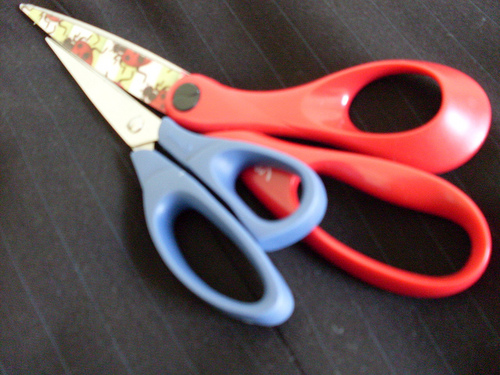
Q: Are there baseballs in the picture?
A: No, there are no baseballs.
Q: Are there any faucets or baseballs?
A: No, there are no baseballs or faucets.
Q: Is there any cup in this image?
A: No, there are no cups.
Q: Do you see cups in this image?
A: No, there are no cups.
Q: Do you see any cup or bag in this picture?
A: No, there are no cups or bags.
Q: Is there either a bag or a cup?
A: No, there are no cups or bags.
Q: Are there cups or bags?
A: No, there are no cups or bags.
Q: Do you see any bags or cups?
A: No, there are no cups or bags.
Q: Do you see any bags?
A: No, there are no bags.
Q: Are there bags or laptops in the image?
A: No, there are no bags or laptops.